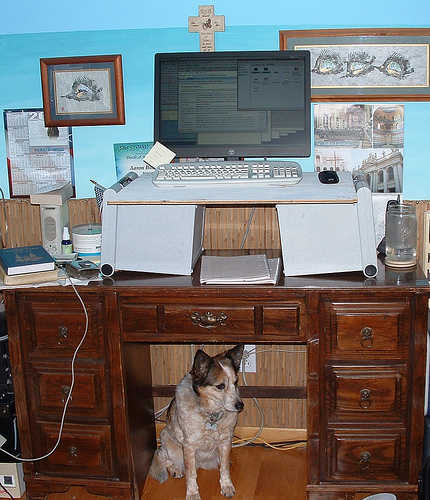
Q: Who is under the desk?
A: A dog.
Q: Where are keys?
A: On the keyboard.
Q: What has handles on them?
A: Drawers.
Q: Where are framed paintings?
A: On blue wall.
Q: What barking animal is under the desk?
A: Dog.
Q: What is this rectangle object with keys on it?
A: Keyboard.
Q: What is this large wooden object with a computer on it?
A: Desk.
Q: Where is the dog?
A: Floor.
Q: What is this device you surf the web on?
A: Computer.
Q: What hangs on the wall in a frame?
A: Picture.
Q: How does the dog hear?
A: Ears.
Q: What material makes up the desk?
A: Wood.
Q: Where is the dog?
A: Under the desk.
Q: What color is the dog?
A: Brown.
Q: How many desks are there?
A: One.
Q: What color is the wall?
A: BLue.